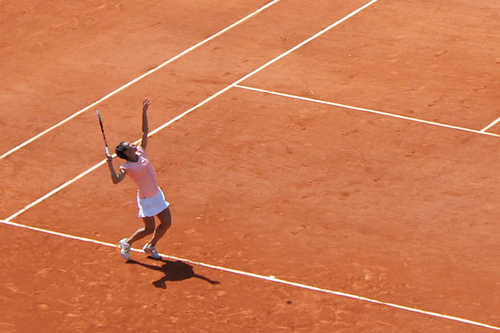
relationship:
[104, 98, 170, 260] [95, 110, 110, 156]
girl holding racket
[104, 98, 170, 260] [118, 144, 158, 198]
girl wearing shirt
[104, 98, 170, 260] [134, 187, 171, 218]
girl wearing skirt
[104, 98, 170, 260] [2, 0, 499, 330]
girl on court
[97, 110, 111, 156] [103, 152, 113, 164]
racket in hand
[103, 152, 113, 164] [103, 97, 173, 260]
hand of player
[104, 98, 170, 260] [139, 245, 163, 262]
girl wearing shoe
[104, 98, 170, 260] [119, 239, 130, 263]
girl wearing shoe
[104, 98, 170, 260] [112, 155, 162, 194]
girl wearing shirt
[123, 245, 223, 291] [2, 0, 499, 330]
player's shadow on court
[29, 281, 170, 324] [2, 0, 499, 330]
footprints on court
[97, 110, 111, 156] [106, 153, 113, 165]
racket in hand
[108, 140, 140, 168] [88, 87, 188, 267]
hair on woman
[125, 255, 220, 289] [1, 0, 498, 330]
player's shadow on ground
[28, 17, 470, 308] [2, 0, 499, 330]
white lines on court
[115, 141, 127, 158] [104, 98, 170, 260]
hair of girl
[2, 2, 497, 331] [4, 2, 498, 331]
lines on tennis court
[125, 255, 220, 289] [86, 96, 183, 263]
player's shadow of player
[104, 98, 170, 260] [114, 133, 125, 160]
girl has hair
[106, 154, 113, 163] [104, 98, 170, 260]
hand of girl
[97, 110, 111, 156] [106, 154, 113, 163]
racket in hand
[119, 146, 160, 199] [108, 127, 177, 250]
shirt on woman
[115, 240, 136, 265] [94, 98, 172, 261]
shoe on player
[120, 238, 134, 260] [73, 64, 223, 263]
shoe on player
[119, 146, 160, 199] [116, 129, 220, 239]
shirt on player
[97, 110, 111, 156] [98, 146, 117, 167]
racket in hand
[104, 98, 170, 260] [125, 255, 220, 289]
girl has player's shadow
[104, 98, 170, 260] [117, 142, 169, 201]
girl wearing shirt